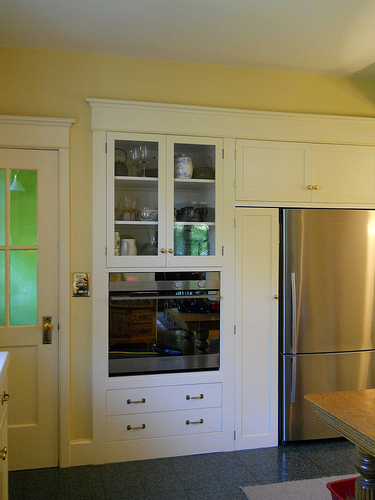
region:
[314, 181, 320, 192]
handle on kitchen cabinet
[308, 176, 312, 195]
handle on kitchen cabinet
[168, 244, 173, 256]
handle on kitchen cabinet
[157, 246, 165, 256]
handle on kitchen cabinet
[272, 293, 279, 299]
handle on kitchen cabinet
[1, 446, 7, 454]
handle on kitchen cabinet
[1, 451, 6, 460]
handle on kitchen cabinet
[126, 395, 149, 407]
handle on kitchen drawer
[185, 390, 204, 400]
handle on kitchen drawer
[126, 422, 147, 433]
handle on kitchen drawer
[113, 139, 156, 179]
window on a cabinet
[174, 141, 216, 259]
window on a cabinet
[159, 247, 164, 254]
golden knob on a cabinet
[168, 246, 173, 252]
golden knob on a cabinet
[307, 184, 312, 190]
golden knob on a cabinet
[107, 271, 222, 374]
an oven on a wall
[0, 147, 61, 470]
a white door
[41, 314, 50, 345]
door knob is gold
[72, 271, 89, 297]
a light switch on the wall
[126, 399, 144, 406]
handle on a drawer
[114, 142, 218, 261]
cabinets in kitchen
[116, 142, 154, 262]
glass window on cabinets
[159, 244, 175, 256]
golden door knobs on cabinets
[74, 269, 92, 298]
light switch on the wall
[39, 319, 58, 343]
golden door knob on door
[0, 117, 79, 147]
white frame of door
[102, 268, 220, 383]
black oven in kitchen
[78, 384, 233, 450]
drawers below the oven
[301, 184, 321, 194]
golden knobs on cabinets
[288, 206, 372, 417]
silver fridge in corner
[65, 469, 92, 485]
gray tile on floor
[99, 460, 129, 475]
gray tile on floor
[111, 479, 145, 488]
gray tile on floor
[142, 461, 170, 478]
gray tile on floor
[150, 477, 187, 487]
gray tile on floor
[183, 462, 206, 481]
gray tile on floor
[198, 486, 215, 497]
gray tile on floor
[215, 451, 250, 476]
gray tile on floor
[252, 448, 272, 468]
gray tile on floor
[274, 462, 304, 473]
gray tile on floor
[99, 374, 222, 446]
Two white rectangular kitchen drawers.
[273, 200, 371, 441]
Silver metal refrigerator and freezer.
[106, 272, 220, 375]
Black and silver kitchen oven.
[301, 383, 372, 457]
Brown granite kitchen counter.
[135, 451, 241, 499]
Square black kitchen floor tile.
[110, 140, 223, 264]
Kitchen cabinet with clear windows.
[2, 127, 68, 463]
White kitchen door with windows.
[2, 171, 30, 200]
White and gold light fixture through window.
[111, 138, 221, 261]
White shelves seen through cabinet.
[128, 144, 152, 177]
Two clear empty wine glasses.